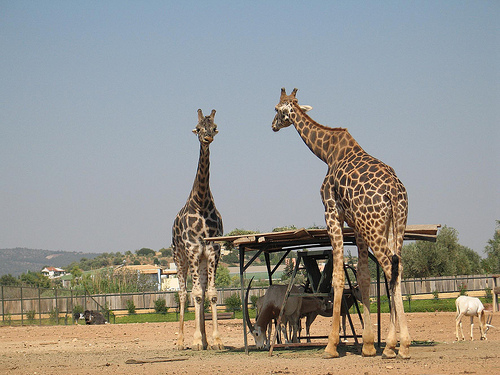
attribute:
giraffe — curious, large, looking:
[174, 85, 242, 171]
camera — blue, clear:
[0, 1, 492, 363]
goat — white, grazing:
[444, 284, 500, 340]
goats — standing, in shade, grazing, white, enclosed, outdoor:
[223, 253, 373, 372]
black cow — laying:
[78, 299, 127, 334]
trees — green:
[62, 262, 182, 311]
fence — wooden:
[10, 287, 196, 327]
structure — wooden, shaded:
[211, 209, 457, 373]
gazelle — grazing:
[433, 265, 498, 349]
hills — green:
[9, 232, 100, 282]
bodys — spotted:
[308, 118, 419, 225]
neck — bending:
[289, 116, 366, 164]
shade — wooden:
[210, 202, 468, 272]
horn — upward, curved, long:
[233, 271, 264, 336]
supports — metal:
[222, 234, 288, 356]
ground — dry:
[9, 319, 168, 374]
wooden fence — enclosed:
[3, 262, 492, 311]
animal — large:
[64, 292, 129, 336]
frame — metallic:
[229, 238, 270, 353]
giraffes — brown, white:
[144, 66, 480, 370]